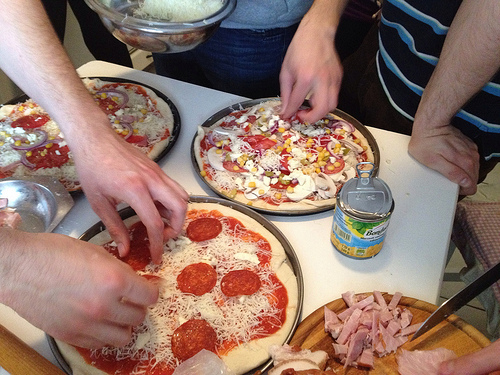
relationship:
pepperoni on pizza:
[175, 263, 218, 298] [53, 202, 295, 375]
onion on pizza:
[95, 85, 130, 117] [53, 202, 295, 375]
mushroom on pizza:
[313, 171, 337, 198] [53, 202, 295, 375]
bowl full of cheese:
[83, 0, 237, 55] [140, 1, 225, 22]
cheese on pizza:
[140, 1, 225, 22] [53, 202, 295, 375]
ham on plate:
[343, 332, 368, 373] [289, 293, 495, 374]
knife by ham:
[408, 263, 498, 347] [343, 332, 368, 373]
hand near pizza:
[72, 130, 189, 264] [53, 202, 295, 375]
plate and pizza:
[289, 293, 495, 374] [53, 202, 295, 375]